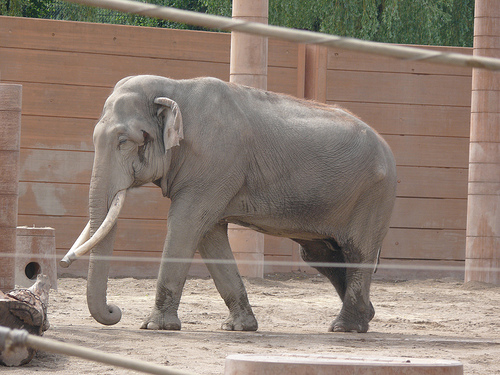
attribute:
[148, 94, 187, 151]
ear — small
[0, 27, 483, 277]
wall — wooden, brown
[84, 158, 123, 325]
trunk — elephants, curled, up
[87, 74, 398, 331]
elephant — gray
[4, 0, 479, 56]
trees — green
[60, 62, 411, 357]
elephant — living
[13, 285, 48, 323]
chain — wrapped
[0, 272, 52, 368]
log — wooden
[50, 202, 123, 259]
white tusk — long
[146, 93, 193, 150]
ear — gray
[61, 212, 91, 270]
tusk — sawed off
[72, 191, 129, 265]
tusk — sawed off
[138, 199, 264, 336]
legs — straight, elephants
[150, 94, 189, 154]
ear — elephants, small, baby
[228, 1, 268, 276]
support beam — large